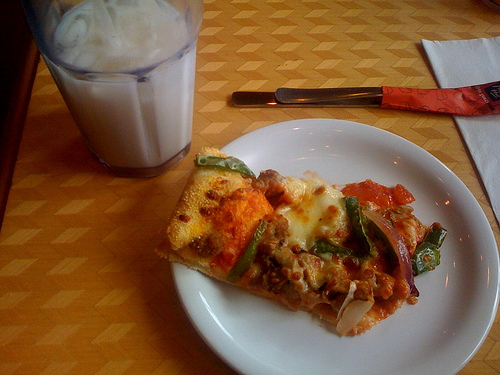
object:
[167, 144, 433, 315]
pizza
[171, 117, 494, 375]
plate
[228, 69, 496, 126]
silverware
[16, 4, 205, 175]
cup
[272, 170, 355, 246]
cheese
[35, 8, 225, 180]
glass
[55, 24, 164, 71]
ice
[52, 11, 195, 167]
milk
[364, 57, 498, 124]
paper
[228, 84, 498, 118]
utensils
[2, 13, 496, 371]
table